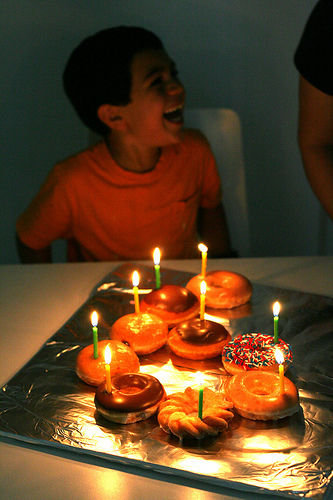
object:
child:
[13, 22, 236, 263]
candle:
[195, 371, 205, 418]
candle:
[273, 347, 286, 396]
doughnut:
[224, 366, 302, 423]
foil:
[0, 262, 333, 496]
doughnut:
[219, 328, 294, 374]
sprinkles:
[222, 328, 293, 372]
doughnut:
[93, 371, 166, 427]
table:
[0, 254, 333, 500]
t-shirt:
[13, 127, 225, 264]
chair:
[188, 102, 253, 258]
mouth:
[161, 100, 189, 129]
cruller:
[157, 385, 235, 438]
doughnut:
[108, 309, 169, 355]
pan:
[0, 255, 332, 496]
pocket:
[171, 189, 200, 246]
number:
[75, 268, 299, 441]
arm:
[294, 0, 333, 216]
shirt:
[289, 0, 333, 100]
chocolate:
[175, 317, 229, 348]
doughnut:
[165, 316, 231, 362]